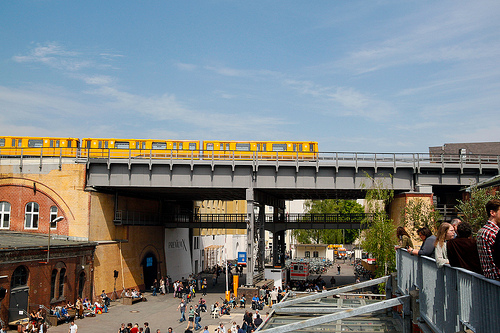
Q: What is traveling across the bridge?
A: A train.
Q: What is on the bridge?
A: A train.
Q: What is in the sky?
A: Clouds.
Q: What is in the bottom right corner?
A: Men and women.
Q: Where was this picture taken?
A: A train station.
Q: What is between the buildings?
A: A walkway.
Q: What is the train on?
A: A bridge.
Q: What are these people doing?
A: Waiting.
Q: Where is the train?
A: On top of the bridge?.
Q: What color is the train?
A: Yellow.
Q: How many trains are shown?
A: One.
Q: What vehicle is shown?
A: A train.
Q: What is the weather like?
A: Slightly cloudy.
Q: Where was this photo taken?
A: A bridge.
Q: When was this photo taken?
A: Day time.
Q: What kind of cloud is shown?
A: Stratus.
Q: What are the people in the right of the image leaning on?
A: A fence.